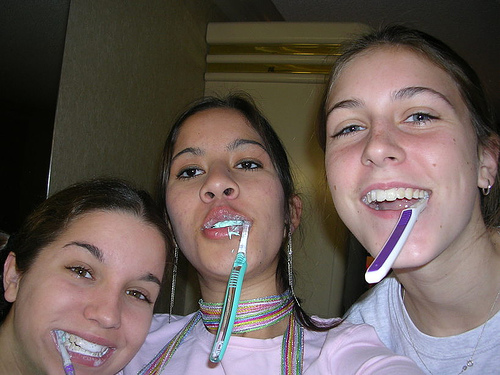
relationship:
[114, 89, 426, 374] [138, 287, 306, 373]
girl wearing scarf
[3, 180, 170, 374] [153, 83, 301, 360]
girl to left of girl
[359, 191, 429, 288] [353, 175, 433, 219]
toothbrush inside mouth